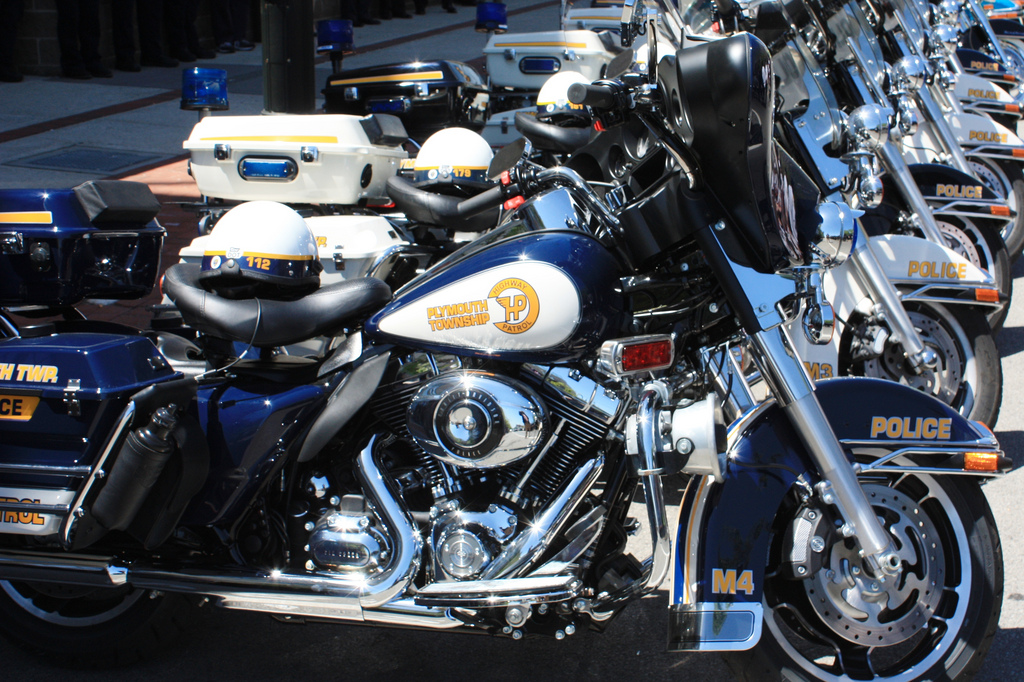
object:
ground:
[835, 377, 896, 429]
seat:
[161, 257, 374, 352]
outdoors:
[66, 3, 983, 645]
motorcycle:
[0, 188, 1021, 680]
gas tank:
[373, 228, 628, 362]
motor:
[373, 392, 627, 631]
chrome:
[382, 490, 549, 615]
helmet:
[198, 193, 323, 292]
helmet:
[407, 123, 494, 187]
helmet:
[529, 63, 590, 112]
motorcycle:
[154, 114, 1013, 440]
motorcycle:
[169, 110, 1014, 280]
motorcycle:
[561, 0, 1020, 64]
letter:
[512, 292, 528, 320]